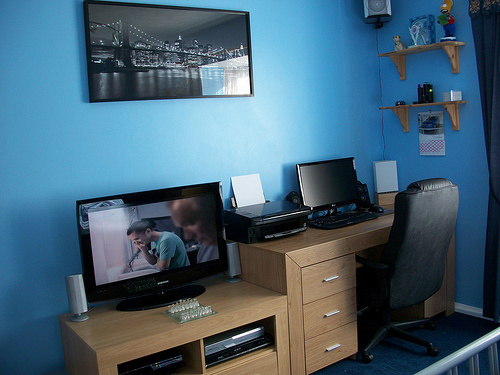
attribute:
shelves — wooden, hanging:
[373, 39, 464, 133]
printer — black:
[226, 196, 312, 243]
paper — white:
[229, 168, 270, 209]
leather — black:
[359, 178, 462, 316]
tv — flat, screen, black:
[75, 180, 230, 315]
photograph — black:
[84, 1, 256, 104]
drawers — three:
[300, 252, 362, 374]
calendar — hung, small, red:
[417, 109, 450, 155]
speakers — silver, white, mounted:
[66, 240, 242, 323]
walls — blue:
[0, 0, 485, 374]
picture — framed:
[81, 2, 254, 105]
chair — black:
[358, 178, 460, 365]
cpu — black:
[297, 157, 384, 232]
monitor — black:
[294, 157, 363, 214]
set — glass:
[164, 297, 219, 326]